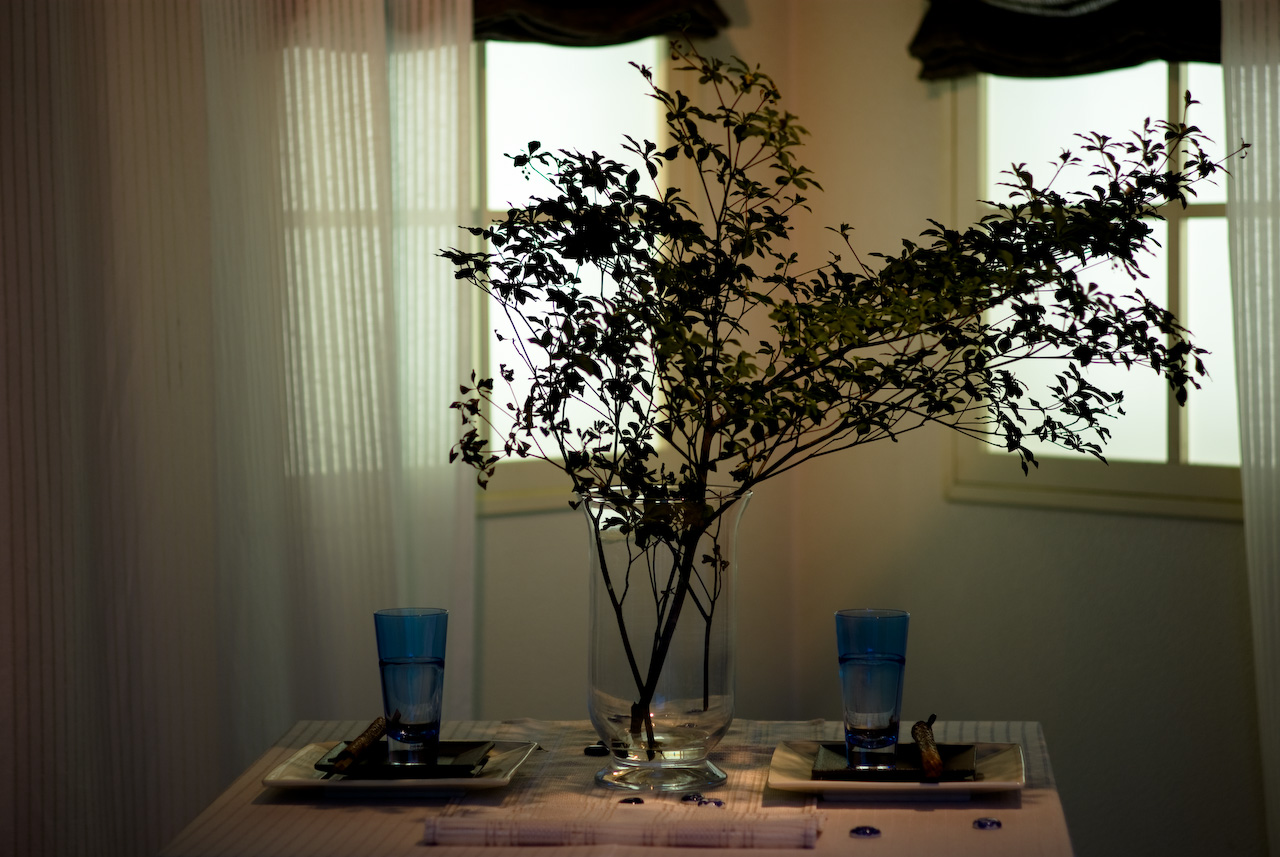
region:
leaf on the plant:
[574, 366, 628, 419]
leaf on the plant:
[799, 329, 820, 367]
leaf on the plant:
[658, 223, 687, 252]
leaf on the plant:
[480, 260, 501, 287]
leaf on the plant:
[612, 454, 668, 485]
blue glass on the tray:
[363, 587, 461, 773]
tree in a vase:
[451, 48, 1224, 594]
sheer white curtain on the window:
[232, 9, 493, 473]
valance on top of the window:
[890, 6, 1228, 75]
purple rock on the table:
[844, 818, 889, 847]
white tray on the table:
[758, 759, 1041, 799]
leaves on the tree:
[896, 269, 1034, 351]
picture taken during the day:
[471, 46, 1180, 503]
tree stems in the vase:
[508, 93, 1078, 626]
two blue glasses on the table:
[371, 597, 921, 737]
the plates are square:
[769, 742, 1004, 798]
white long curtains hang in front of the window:
[104, 7, 488, 700]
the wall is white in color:
[985, 539, 1184, 698]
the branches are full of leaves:
[583, 118, 976, 434]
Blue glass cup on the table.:
[358, 576, 456, 736]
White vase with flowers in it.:
[577, 459, 734, 813]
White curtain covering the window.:
[76, 64, 588, 693]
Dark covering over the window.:
[896, 6, 1247, 119]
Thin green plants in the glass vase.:
[464, 72, 932, 733]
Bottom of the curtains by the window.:
[1225, 613, 1272, 660]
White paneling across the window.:
[237, 152, 661, 228]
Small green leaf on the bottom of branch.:
[1016, 423, 1056, 499]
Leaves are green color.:
[516, 182, 1042, 425]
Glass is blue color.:
[352, 590, 951, 765]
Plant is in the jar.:
[514, 239, 771, 804]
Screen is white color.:
[255, 70, 472, 613]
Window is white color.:
[915, 65, 1236, 553]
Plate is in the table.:
[251, 703, 1035, 838]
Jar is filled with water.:
[551, 473, 764, 807]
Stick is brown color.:
[587, 518, 738, 775]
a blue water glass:
[365, 598, 452, 742]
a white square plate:
[734, 711, 1052, 818]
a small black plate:
[818, 728, 982, 786]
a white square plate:
[259, 722, 555, 804]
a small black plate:
[321, 724, 502, 780]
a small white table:
[118, 680, 1083, 853]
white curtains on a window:
[1, 323, 529, 747]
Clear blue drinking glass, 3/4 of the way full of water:
[369, 602, 453, 775]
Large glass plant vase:
[563, 479, 745, 799]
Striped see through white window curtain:
[204, 0, 481, 850]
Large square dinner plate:
[259, 730, 547, 797]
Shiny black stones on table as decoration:
[610, 787, 1019, 843]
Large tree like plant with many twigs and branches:
[429, 42, 1257, 762]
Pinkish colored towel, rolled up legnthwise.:
[409, 801, 827, 852]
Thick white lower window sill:
[943, 448, 1277, 528]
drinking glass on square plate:
[262, 602, 538, 788]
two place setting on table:
[177, 599, 1073, 853]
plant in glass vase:
[441, 43, 1236, 800]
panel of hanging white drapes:
[6, 0, 475, 850]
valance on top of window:
[905, 0, 1278, 525]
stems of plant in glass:
[580, 486, 750, 791]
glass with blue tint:
[377, 607, 448, 764]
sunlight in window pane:
[479, 42, 667, 215]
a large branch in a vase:
[444, 43, 1255, 781]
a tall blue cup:
[377, 604, 450, 766]